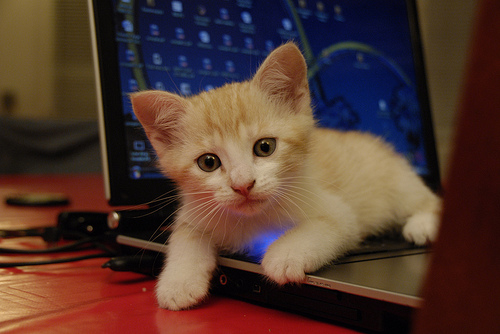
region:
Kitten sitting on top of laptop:
[86, 2, 447, 328]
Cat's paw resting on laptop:
[262, 235, 329, 285]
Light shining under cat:
[226, 225, 293, 272]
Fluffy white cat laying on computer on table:
[85, 4, 447, 330]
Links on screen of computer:
[91, 3, 440, 206]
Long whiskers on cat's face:
[131, 135, 351, 256]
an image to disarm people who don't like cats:
[130, 42, 441, 309]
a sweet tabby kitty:
[130, 38, 445, 305]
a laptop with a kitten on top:
[85, 0, 436, 329]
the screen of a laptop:
[92, 0, 435, 202]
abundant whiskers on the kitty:
[152, 186, 233, 238]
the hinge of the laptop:
[103, 202, 148, 229]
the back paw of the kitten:
[402, 213, 434, 245]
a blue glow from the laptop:
[246, 222, 286, 257]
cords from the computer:
[0, 237, 106, 277]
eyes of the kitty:
[188, 125, 288, 177]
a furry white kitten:
[127, 38, 442, 312]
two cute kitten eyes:
[190, 133, 277, 174]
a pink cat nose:
[228, 176, 256, 195]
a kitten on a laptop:
[83, 1, 444, 333]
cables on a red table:
[0, 208, 162, 272]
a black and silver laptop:
[85, 2, 444, 332]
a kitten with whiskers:
[126, 43, 443, 310]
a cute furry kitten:
[127, 38, 442, 310]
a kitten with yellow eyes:
[127, 41, 442, 313]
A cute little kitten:
[131, 38, 459, 313]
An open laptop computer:
[72, 4, 474, 321]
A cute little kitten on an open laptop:
[80, 3, 467, 318]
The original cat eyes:
[188, 132, 285, 172]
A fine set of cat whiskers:
[146, 150, 315, 245]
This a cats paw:
[146, 258, 217, 318]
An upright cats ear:
[248, 40, 323, 118]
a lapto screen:
[119, 2, 434, 173]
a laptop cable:
[9, 215, 109, 272]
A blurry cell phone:
[6, 182, 71, 212]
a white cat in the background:
[98, 36, 453, 322]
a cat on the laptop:
[56, 5, 441, 327]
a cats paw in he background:
[246, 236, 391, 331]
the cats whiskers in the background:
[142, 85, 407, 275]